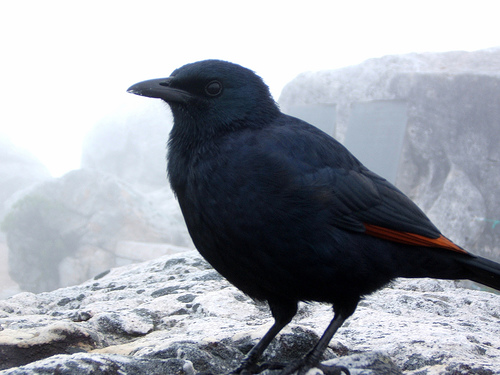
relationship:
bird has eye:
[126, 59, 500, 375] [203, 82, 223, 97]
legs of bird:
[237, 302, 350, 373] [126, 59, 500, 375]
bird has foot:
[126, 59, 500, 375] [279, 357, 355, 373]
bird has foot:
[126, 59, 500, 375] [221, 363, 285, 373]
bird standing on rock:
[126, 45, 429, 315] [72, 258, 466, 372]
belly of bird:
[179, 195, 267, 304] [144, 26, 426, 324]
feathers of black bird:
[268, 130, 489, 270] [81, 49, 461, 338]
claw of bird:
[248, 359, 298, 371] [126, 59, 500, 375]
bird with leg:
[126, 59, 500, 375] [282, 296, 363, 371]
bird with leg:
[126, 59, 500, 375] [221, 300, 296, 372]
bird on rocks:
[126, 59, 500, 375] [15, 264, 497, 371]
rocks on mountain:
[111, 286, 179, 321] [0, 38, 500, 373]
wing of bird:
[229, 117, 498, 284] [90, 38, 489, 373]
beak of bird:
[104, 70, 171, 112] [126, 59, 500, 375]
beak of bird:
[127, 76, 199, 109] [126, 59, 500, 375]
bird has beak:
[126, 59, 500, 375] [128, 81, 190, 99]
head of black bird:
[129, 60, 278, 126] [125, 60, 498, 373]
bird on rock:
[126, 59, 500, 375] [226, 315, 338, 360]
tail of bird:
[395, 234, 497, 289] [126, 59, 500, 375]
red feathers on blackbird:
[375, 217, 408, 265] [110, 67, 375, 279]